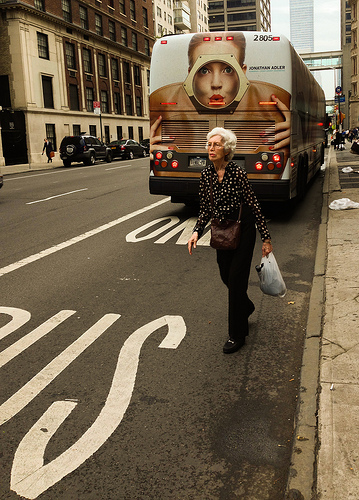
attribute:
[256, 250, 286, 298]
bag — plastic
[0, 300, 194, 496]
letters — white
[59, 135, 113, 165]
car — parked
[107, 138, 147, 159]
car — parked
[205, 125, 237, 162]
hair — white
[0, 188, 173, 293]
lines — painted, white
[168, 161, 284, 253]
shirt — black, white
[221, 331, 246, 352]
shoe — black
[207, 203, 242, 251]
purse — brown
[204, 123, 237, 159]
hair — gray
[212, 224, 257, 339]
pants — black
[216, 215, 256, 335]
pants — black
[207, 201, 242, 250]
bag — brown